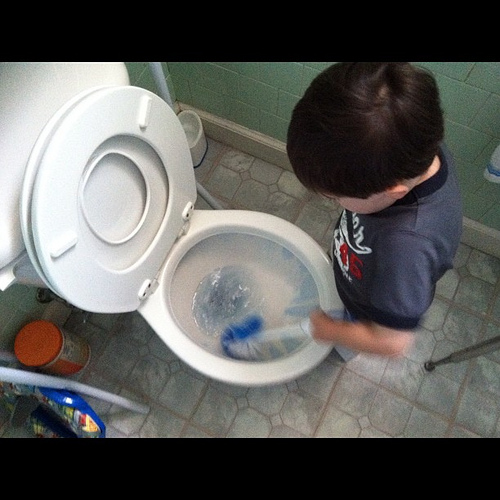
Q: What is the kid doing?
A: Cleaning the toilet.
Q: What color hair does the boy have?
A: Black.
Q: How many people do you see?
A: 1.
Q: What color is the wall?
A: Green.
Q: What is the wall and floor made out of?
A: Tile.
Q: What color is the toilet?
A: White.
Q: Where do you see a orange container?
A: Left side behind the toilet.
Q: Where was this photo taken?
A: A bathroom.